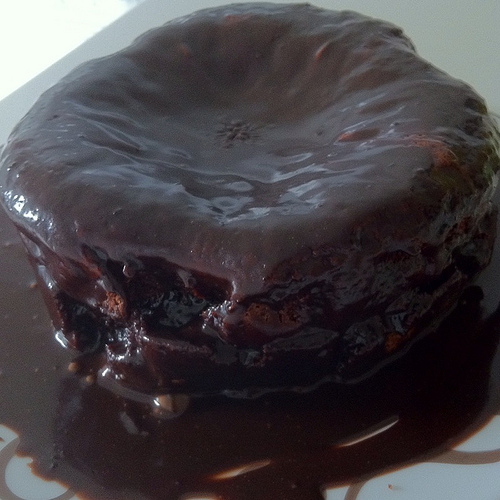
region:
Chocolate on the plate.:
[29, 423, 151, 496]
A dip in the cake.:
[82, 43, 399, 220]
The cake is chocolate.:
[92, 263, 279, 398]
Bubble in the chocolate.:
[141, 380, 186, 422]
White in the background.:
[8, 5, 78, 56]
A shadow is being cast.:
[91, 15, 140, 48]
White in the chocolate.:
[322, 411, 414, 454]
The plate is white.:
[393, 471, 488, 498]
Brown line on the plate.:
[421, 433, 499, 465]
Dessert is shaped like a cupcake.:
[3, 7, 498, 402]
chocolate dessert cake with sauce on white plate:
[0, 0, 497, 499]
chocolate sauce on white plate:
[28, 386, 234, 498]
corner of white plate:
[400, 473, 499, 498]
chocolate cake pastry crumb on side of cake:
[204, 298, 299, 343]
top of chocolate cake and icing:
[1, 0, 498, 290]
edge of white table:
[1, 2, 145, 130]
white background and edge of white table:
[0, 4, 142, 96]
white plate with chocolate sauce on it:
[305, 413, 434, 473]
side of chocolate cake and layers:
[301, 225, 428, 396]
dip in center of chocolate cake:
[158, 63, 323, 185]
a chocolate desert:
[10, 15, 467, 470]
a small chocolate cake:
[12, 0, 475, 432]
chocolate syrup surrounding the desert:
[4, 242, 439, 498]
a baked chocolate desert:
[7, 10, 488, 476]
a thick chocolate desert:
[15, 16, 494, 410]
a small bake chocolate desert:
[12, 24, 437, 407]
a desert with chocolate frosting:
[5, 25, 445, 407]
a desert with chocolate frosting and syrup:
[1, 15, 471, 490]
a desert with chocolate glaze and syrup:
[25, 35, 422, 448]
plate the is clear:
[245, 419, 356, 492]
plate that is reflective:
[28, 403, 112, 485]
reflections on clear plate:
[47, 408, 452, 493]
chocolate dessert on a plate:
[55, 31, 472, 330]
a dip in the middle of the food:
[44, 14, 425, 234]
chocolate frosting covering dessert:
[63, 19, 420, 339]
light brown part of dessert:
[77, 281, 171, 338]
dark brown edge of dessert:
[172, 280, 462, 401]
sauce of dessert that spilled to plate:
[128, 380, 230, 420]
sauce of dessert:
[21, 77, 186, 254]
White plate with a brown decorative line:
[401, 446, 496, 491]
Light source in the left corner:
[0, 1, 110, 62]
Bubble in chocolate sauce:
[20, 275, 40, 292]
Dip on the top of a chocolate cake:
[110, 35, 391, 220]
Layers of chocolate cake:
[220, 275, 392, 367]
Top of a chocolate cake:
[196, 0, 356, 30]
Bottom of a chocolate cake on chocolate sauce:
[85, 350, 370, 410]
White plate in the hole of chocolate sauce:
[301, 406, 412, 451]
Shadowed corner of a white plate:
[403, 4, 497, 46]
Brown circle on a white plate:
[1, 435, 78, 496]